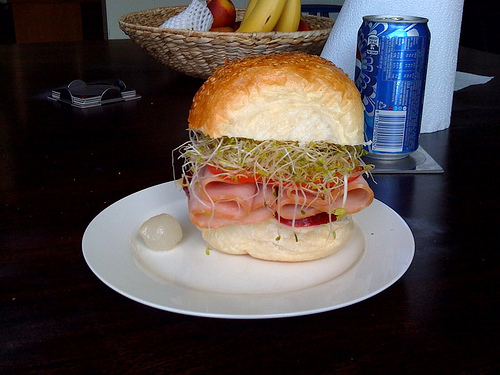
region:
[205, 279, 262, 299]
plate on the counter.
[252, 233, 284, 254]
bun on the plate.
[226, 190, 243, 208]
meat on the sandwich.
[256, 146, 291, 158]
sprouts on the sandwich.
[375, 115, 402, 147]
label on the can.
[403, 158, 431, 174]
coaster under the can.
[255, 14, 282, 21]
bananas in the basket.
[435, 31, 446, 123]
roll of paper towels.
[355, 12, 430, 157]
aluminum can of soda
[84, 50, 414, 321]
a sandwich on a white plate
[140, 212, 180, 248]
a white pearl onion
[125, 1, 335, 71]
a wicker basket of fruit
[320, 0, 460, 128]
a white roll of paper towels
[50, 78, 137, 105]
a black coaster holder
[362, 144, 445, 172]
a coaster under the soda can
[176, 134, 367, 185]
bean sprouts on the sandwich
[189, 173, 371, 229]
pieces of ham on the sandwich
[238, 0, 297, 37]
bananas in the basket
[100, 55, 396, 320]
a sandwich on a plate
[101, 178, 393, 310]
a white plate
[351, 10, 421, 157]
a can of cola on the table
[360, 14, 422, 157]
a blue can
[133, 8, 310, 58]
a basket of fruit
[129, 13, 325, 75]
a brown basket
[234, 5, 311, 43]
bananas in a bowl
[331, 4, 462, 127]
a roll of paper towels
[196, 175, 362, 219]
the meat on the sandwich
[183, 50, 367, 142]
the bread on the sandwich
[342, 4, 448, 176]
a can of Pepsi soda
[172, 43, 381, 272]
a large sandwich with many toppings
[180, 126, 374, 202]
green sprouts on a sandwich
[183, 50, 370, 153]
a large sandwich bun with sesame seeds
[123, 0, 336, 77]
a fruit basket containing peaches and bananas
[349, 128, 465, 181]
a coaster under a soda can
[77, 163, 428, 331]
a white plate for food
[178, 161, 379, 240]
sandwich meats layered on a sandwich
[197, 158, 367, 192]
tomatoes layered between sprouts and lunch meat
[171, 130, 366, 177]
white and green alfalfa sprouts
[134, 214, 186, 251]
one large pearl onion on plate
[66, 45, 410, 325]
one sandwich on white plate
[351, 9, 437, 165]
one blue can of soda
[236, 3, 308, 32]
middle view of several bananas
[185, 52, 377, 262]
meat sandwich on white bun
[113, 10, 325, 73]
one light colored woven basket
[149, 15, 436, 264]
one sandwich with soda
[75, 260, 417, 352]
white round plate on black table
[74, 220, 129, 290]
curved edge of round white plate